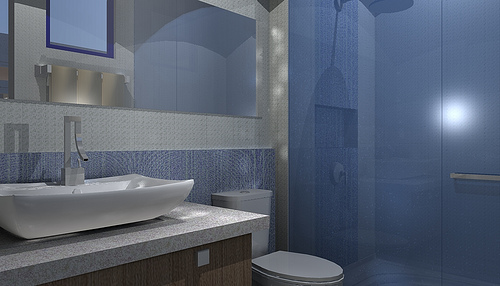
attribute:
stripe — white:
[2, 101, 283, 150]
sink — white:
[1, 180, 203, 232]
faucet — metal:
[59, 117, 93, 183]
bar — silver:
[445, 170, 497, 184]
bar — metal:
[442, 161, 487, 196]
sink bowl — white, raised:
[2, 162, 202, 242]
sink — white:
[21, 171, 176, 251]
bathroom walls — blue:
[362, 17, 491, 172]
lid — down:
[251, 247, 344, 282]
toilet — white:
[210, 186, 347, 284]